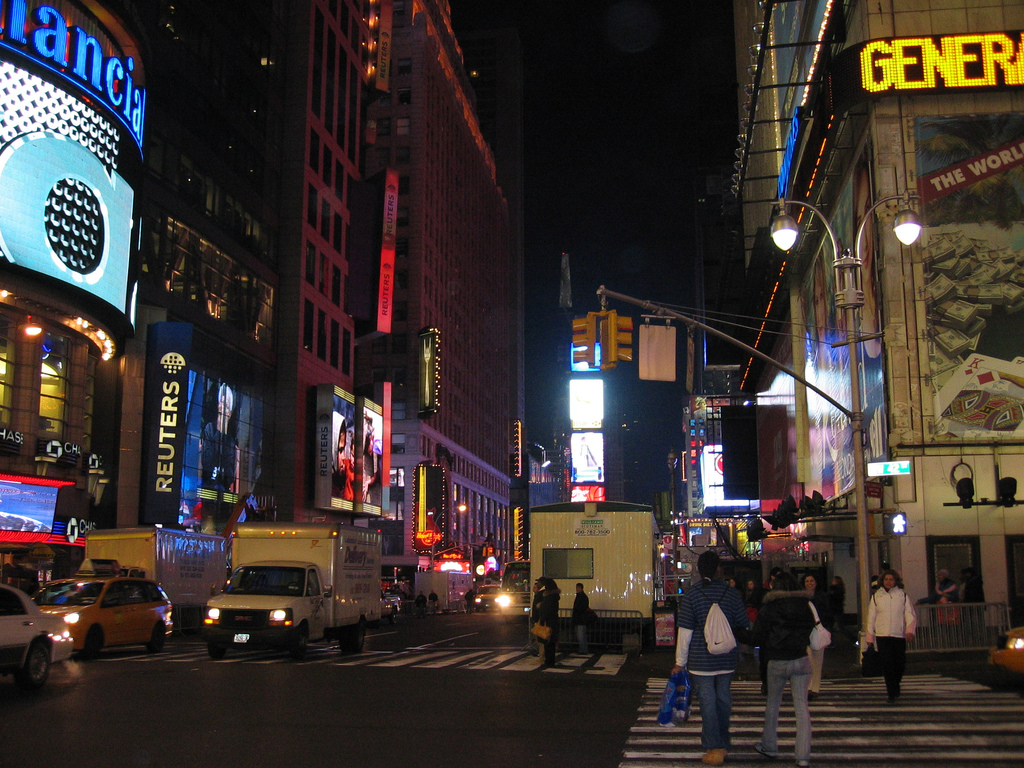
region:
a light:
[761, 203, 816, 261]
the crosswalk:
[389, 637, 487, 683]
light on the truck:
[266, 601, 295, 628]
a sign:
[862, 36, 1014, 109]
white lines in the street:
[835, 705, 941, 759]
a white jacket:
[876, 593, 909, 631]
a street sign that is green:
[864, 454, 925, 486]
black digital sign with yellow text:
[857, 30, 1022, 106]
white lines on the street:
[127, 621, 1020, 765]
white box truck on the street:
[192, 518, 390, 662]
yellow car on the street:
[44, 575, 172, 662]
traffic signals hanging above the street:
[566, 304, 636, 375]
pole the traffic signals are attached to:
[609, 288, 843, 435]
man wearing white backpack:
[660, 542, 753, 746]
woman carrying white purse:
[752, 569, 836, 750]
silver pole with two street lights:
[762, 177, 952, 677]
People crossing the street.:
[629, 535, 1021, 764]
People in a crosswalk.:
[621, 535, 1021, 766]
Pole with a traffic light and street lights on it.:
[567, 187, 923, 672]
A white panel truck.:
[204, 515, 391, 653]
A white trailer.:
[514, 486, 664, 641]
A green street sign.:
[868, 455, 911, 484]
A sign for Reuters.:
[130, 303, 204, 528]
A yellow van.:
[38, 569, 176, 665]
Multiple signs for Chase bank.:
[2, 426, 123, 544]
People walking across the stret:
[558, 473, 888, 762]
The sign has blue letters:
[10, 0, 232, 163]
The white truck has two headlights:
[182, 514, 392, 692]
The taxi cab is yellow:
[19, 533, 204, 696]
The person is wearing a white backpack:
[605, 524, 745, 766]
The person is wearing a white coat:
[823, 508, 963, 744]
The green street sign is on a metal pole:
[819, 389, 971, 620]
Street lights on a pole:
[763, 211, 928, 256]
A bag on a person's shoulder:
[798, 601, 830, 652]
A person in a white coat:
[857, 563, 924, 690]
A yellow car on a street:
[43, 575, 180, 658]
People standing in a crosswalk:
[525, 578, 599, 681]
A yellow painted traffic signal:
[566, 306, 637, 376]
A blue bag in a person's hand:
[649, 667, 694, 729]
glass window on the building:
[304, 296, 315, 355]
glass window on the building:
[317, 311, 327, 365]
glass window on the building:
[330, 318, 335, 366]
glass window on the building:
[340, 324, 347, 382]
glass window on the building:
[339, 270, 352, 315]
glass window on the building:
[327, 261, 335, 306]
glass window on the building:
[314, 254, 327, 297]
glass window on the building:
[301, 235, 317, 283]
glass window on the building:
[329, 204, 337, 243]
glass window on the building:
[321, 199, 335, 245]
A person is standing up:
[667, 557, 754, 754]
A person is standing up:
[850, 567, 915, 689]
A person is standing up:
[795, 569, 831, 678]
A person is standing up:
[723, 569, 750, 601]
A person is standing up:
[575, 577, 596, 653]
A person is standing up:
[536, 573, 562, 665]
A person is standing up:
[745, 577, 762, 615]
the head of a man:
[684, 537, 733, 595]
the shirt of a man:
[667, 590, 766, 686]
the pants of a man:
[684, 663, 754, 753]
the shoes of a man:
[690, 736, 728, 765]